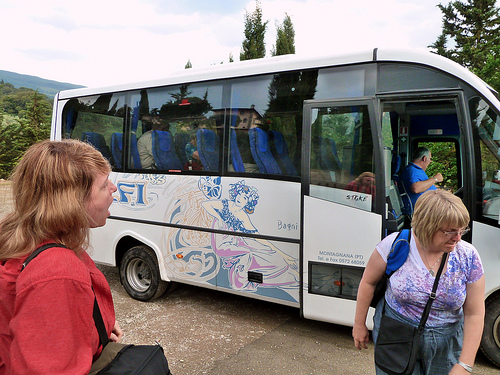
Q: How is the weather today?
A: It is cloudy.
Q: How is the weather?
A: It is cloudy.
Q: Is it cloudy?
A: Yes, it is cloudy.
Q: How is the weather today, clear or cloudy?
A: It is cloudy.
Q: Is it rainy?
A: No, it is cloudy.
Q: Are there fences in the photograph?
A: No, there are no fences.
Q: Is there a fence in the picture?
A: No, there are no fences.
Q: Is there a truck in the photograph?
A: No, there are no trucks.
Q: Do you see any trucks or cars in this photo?
A: No, there are no trucks or cars.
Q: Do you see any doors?
A: Yes, there is a door.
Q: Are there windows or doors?
A: Yes, there is a door.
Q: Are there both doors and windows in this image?
A: Yes, there are both a door and a window.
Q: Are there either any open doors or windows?
A: Yes, there is an open door.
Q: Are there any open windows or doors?
A: Yes, there is an open door.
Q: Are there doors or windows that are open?
A: Yes, the door is open.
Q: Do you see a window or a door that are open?
A: Yes, the door is open.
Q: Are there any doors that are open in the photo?
A: Yes, there is an open door.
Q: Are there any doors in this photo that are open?
A: Yes, there is a door that is open.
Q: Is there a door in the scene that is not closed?
A: Yes, there is a open door.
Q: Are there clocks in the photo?
A: No, there are no clocks.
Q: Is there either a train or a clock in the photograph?
A: No, there are no clocks or trains.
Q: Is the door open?
A: Yes, the door is open.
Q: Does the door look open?
A: Yes, the door is open.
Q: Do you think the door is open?
A: Yes, the door is open.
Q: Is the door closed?
A: No, the door is open.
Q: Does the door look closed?
A: No, the door is open.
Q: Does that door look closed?
A: No, the door is open.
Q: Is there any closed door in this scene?
A: No, there is a door but it is open.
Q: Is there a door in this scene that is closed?
A: No, there is a door but it is open.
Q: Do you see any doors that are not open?
A: No, there is a door but it is open.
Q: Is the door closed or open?
A: The door is open.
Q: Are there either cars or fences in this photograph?
A: No, there are no fences or cars.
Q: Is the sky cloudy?
A: Yes, the sky is cloudy.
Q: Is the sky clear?
A: No, the sky is cloudy.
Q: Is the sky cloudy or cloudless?
A: The sky is cloudy.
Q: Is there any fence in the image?
A: No, there are no fences.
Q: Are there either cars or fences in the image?
A: No, there are no fences or cars.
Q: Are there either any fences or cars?
A: No, there are no fences or cars.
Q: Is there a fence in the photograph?
A: No, there are no fences.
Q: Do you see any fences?
A: No, there are no fences.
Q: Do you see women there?
A: Yes, there is a woman.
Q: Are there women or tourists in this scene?
A: Yes, there is a woman.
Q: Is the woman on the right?
A: Yes, the woman is on the right of the image.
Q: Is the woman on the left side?
A: No, the woman is on the right of the image.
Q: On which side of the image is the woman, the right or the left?
A: The woman is on the right of the image.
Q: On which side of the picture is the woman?
A: The woman is on the right of the image.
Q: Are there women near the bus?
A: Yes, there is a woman near the bus.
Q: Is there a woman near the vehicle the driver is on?
A: Yes, there is a woman near the bus.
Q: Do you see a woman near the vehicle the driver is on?
A: Yes, there is a woman near the bus.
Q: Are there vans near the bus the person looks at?
A: No, there is a woman near the bus.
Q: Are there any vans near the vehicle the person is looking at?
A: No, there is a woman near the bus.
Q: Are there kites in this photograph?
A: No, there are no kites.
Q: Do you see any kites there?
A: No, there are no kites.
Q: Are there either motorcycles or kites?
A: No, there are no kites or motorcycles.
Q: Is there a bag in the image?
A: Yes, there is a bag.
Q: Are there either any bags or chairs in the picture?
A: Yes, there is a bag.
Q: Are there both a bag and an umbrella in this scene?
A: No, there is a bag but no umbrellas.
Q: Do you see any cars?
A: No, there are no cars.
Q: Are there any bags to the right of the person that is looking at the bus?
A: Yes, there is a bag to the right of the person.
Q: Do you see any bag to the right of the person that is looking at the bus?
A: Yes, there is a bag to the right of the person.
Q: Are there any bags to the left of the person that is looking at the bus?
A: No, the bag is to the right of the person.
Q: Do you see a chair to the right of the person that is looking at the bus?
A: No, there is a bag to the right of the person.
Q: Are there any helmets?
A: No, there are no helmets.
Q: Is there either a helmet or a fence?
A: No, there are no helmets or fences.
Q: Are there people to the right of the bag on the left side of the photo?
A: No, the person is to the left of the bag.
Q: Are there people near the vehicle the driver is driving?
A: Yes, there is a person near the bus.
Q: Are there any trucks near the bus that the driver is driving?
A: No, there is a person near the bus.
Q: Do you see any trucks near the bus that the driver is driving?
A: No, there is a person near the bus.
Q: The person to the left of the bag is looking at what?
A: The person is looking at the bus.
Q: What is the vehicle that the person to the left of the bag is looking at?
A: The vehicle is a bus.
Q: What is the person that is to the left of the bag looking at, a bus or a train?
A: The person is looking at a bus.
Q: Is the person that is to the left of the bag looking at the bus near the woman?
A: Yes, the person is looking at the bus.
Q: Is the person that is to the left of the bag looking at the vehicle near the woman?
A: Yes, the person is looking at the bus.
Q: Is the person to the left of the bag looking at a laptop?
A: No, the person is looking at the bus.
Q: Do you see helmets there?
A: No, there are no helmets.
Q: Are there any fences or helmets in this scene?
A: No, there are no helmets or fences.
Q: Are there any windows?
A: Yes, there is a window.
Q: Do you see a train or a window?
A: Yes, there is a window.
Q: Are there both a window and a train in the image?
A: No, there is a window but no trains.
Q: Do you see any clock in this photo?
A: No, there are no clocks.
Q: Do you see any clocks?
A: No, there are no clocks.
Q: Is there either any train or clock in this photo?
A: No, there are no clocks or trains.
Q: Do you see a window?
A: Yes, there is a window.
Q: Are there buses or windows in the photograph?
A: Yes, there is a window.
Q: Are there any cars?
A: No, there are no cars.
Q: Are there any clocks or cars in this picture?
A: No, there are no cars or clocks.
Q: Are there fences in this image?
A: No, there are no fences.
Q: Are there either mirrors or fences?
A: No, there are no fences or mirrors.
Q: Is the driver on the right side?
A: Yes, the driver is on the right of the image.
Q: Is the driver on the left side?
A: No, the driver is on the right of the image.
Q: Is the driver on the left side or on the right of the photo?
A: The driver is on the right of the image.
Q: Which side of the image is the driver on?
A: The driver is on the right of the image.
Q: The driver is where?
A: The driver is on the bus.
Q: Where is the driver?
A: The driver is on the bus.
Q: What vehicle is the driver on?
A: The driver is on the bus.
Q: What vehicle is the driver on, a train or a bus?
A: The driver is on a bus.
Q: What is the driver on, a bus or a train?
A: The driver is on a bus.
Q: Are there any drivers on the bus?
A: Yes, there is a driver on the bus.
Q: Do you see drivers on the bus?
A: Yes, there is a driver on the bus.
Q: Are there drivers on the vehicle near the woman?
A: Yes, there is a driver on the bus.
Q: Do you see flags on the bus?
A: No, there is a driver on the bus.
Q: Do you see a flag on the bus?
A: No, there is a driver on the bus.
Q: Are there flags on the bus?
A: No, there is a driver on the bus.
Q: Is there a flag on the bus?
A: No, there is a driver on the bus.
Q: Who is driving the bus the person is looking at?
A: The driver is driving the bus.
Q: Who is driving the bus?
A: The driver is driving the bus.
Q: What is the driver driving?
A: The driver is driving the bus.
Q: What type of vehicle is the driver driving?
A: The driver is driving the bus.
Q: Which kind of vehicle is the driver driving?
A: The driver is driving the bus.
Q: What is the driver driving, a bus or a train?
A: The driver is driving a bus.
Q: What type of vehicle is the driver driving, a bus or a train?
A: The driver is driving a bus.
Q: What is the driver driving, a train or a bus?
A: The driver is driving a bus.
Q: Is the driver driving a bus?
A: Yes, the driver is driving a bus.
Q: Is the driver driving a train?
A: No, the driver is driving a bus.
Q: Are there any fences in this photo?
A: No, there are no fences.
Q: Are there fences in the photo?
A: No, there are no fences.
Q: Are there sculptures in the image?
A: No, there are no sculptures.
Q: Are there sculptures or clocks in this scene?
A: No, there are no sculptures or clocks.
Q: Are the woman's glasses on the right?
A: Yes, the glasses are on the right of the image.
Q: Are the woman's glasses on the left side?
A: No, the glasses are on the right of the image.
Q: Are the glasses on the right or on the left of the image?
A: The glasses are on the right of the image.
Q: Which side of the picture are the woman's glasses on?
A: The glasses are on the right of the image.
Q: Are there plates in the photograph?
A: No, there are no plates.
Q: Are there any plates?
A: No, there are no plates.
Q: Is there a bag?
A: Yes, there is a bag.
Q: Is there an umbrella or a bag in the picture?
A: Yes, there is a bag.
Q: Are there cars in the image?
A: No, there are no cars.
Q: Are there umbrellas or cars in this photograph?
A: No, there are no cars or umbrellas.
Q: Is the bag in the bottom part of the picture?
A: Yes, the bag is in the bottom of the image.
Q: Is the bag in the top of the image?
A: No, the bag is in the bottom of the image.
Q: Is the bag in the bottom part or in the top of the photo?
A: The bag is in the bottom of the image.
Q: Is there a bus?
A: Yes, there is a bus.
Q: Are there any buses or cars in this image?
A: Yes, there is a bus.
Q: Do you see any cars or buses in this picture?
A: Yes, there is a bus.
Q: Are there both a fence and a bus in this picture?
A: No, there is a bus but no fences.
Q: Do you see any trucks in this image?
A: No, there are no trucks.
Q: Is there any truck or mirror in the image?
A: No, there are no trucks or mirrors.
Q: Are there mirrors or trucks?
A: No, there are no trucks or mirrors.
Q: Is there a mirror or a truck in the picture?
A: No, there are no trucks or mirrors.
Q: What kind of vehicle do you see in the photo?
A: The vehicle is a bus.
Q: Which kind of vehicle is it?
A: The vehicle is a bus.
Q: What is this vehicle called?
A: This is a bus.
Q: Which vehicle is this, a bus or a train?
A: This is a bus.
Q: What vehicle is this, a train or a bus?
A: This is a bus.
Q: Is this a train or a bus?
A: This is a bus.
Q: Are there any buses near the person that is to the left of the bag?
A: Yes, there is a bus near the person.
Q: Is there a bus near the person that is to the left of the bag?
A: Yes, there is a bus near the person.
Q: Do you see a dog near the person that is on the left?
A: No, there is a bus near the person.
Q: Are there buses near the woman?
A: Yes, there is a bus near the woman.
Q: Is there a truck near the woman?
A: No, there is a bus near the woman.